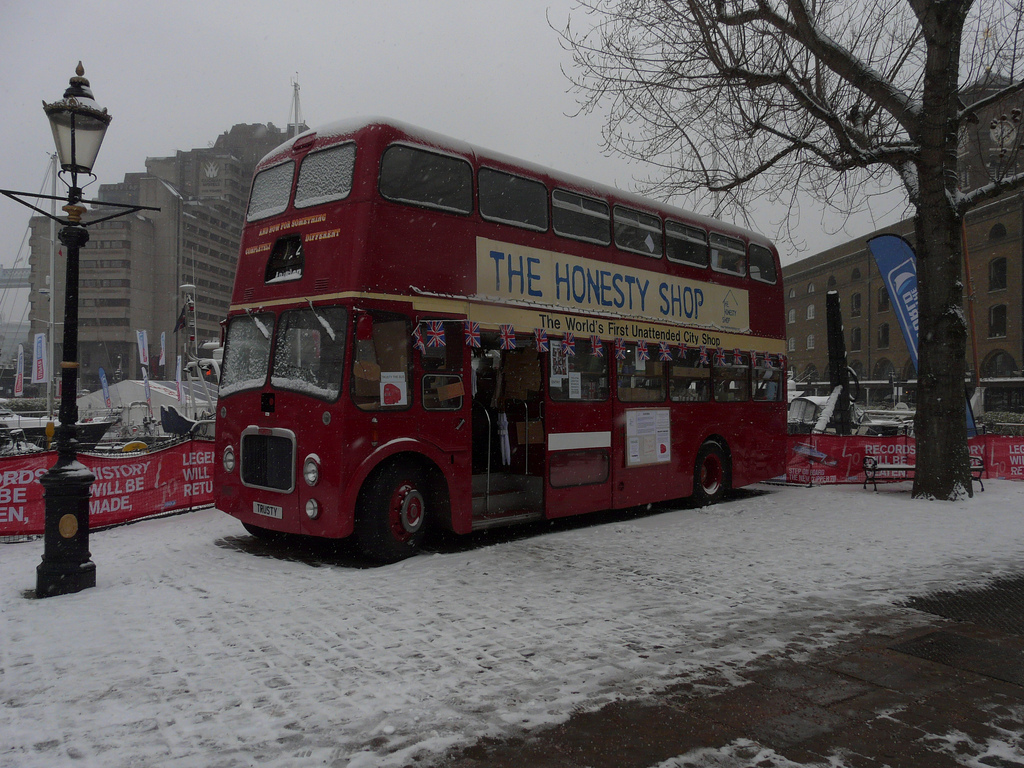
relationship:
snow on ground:
[0, 437, 1022, 767] [1, 434, 1022, 765]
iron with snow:
[0, 58, 164, 597] [38, 59, 116, 117]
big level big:
[205, 113, 789, 569] [205, 113, 789, 569]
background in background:
[785, 0, 1023, 500] [785, 66, 1022, 431]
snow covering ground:
[0, 437, 1022, 767] [1, 434, 1022, 765]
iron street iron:
[0, 58, 164, 597] [0, 58, 164, 597]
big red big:
[205, 113, 789, 569] [205, 113, 789, 569]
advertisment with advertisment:
[476, 236, 749, 334] [476, 236, 749, 334]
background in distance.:
[785, 0, 1023, 500] [785, 66, 1022, 431]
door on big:
[466, 325, 548, 536] [205, 113, 789, 569]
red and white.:
[2, 440, 212, 532] [2, 440, 213, 538]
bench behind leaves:
[860, 452, 987, 499] [544, 4, 1021, 503]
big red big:
[352, 460, 437, 567] [351, 460, 436, 568]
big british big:
[205, 113, 789, 569] [205, 113, 789, 569]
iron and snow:
[0, 58, 164, 597] [0, 437, 1022, 767]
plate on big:
[251, 499, 286, 522] [205, 113, 789, 569]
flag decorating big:
[406, 318, 788, 377] [205, 113, 789, 569]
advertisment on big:
[476, 236, 749, 334] [205, 113, 789, 569]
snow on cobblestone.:
[0, 437, 1022, 767] [417, 578, 1022, 767]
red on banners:
[2, 440, 212, 532] [0, 436, 212, 541]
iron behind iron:
[0, 58, 164, 597] [0, 58, 164, 597]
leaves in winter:
[544, 4, 1021, 503] [0, 0, 1023, 767]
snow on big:
[0, 437, 1022, 767] [205, 113, 789, 569]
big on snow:
[205, 113, 789, 569] [0, 437, 1022, 767]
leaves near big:
[544, 4, 1021, 503] [205, 113, 789, 569]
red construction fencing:
[2, 440, 212, 532] [0, 436, 212, 541]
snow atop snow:
[0, 437, 1022, 767] [0, 437, 1022, 767]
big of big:
[205, 113, 789, 569] [205, 113, 789, 569]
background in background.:
[785, 0, 1023, 500] [785, 66, 1022, 431]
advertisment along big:
[476, 236, 751, 333] [205, 113, 789, 569]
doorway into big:
[466, 325, 548, 536] [205, 113, 789, 569]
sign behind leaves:
[862, 231, 978, 436] [544, 4, 1021, 503]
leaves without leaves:
[544, 4, 1021, 503] [543, 3, 1020, 502]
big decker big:
[205, 113, 789, 569] [205, 113, 789, 569]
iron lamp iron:
[0, 58, 164, 597] [0, 58, 164, 597]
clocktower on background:
[936, 68, 1022, 198] [785, 0, 1023, 500]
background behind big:
[785, 0, 1023, 500] [205, 113, 789, 569]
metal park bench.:
[859, 451, 988, 500] [860, 452, 987, 499]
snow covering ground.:
[0, 437, 1022, 767] [1, 434, 1022, 765]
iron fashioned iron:
[0, 58, 164, 597] [0, 58, 164, 597]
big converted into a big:
[205, 113, 789, 569] [205, 113, 789, 569]